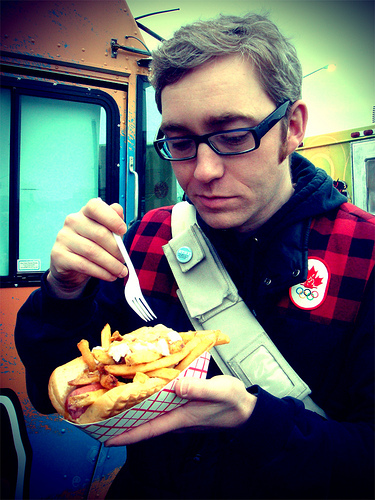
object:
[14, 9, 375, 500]
man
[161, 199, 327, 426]
backpack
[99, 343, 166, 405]
food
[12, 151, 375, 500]
coat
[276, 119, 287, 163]
sideburn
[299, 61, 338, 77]
street lamp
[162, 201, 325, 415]
strap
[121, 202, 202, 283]
shoulder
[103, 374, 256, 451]
hand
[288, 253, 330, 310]
patch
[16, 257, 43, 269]
sticker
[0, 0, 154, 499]
bus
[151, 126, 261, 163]
rim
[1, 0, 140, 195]
structure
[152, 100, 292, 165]
eyeglasses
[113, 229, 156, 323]
fork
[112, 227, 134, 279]
silver handle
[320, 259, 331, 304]
border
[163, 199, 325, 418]
tan strap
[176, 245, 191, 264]
blue button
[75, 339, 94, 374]
fries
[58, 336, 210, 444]
container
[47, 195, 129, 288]
hand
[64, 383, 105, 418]
hot dog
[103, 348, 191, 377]
french fries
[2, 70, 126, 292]
window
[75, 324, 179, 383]
toppings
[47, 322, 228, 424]
bun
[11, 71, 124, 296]
frame